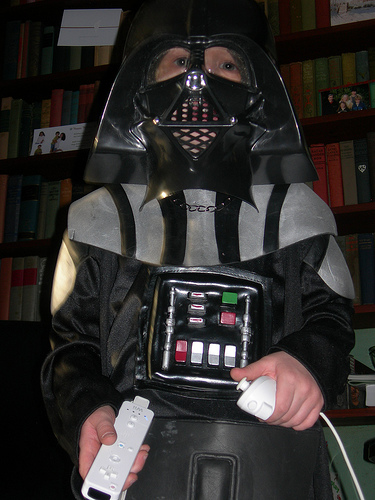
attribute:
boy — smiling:
[45, 1, 353, 498]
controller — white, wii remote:
[81, 395, 154, 499]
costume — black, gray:
[45, 1, 353, 498]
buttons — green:
[222, 292, 237, 306]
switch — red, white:
[174, 339, 188, 365]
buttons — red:
[219, 308, 236, 325]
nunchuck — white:
[77, 393, 155, 499]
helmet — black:
[84, 1, 318, 185]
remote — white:
[233, 372, 277, 423]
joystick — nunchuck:
[237, 372, 275, 423]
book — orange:
[327, 140, 344, 208]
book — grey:
[36, 180, 60, 240]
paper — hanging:
[59, 10, 123, 45]